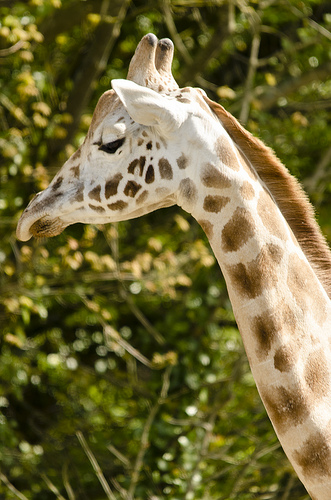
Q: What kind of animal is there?
A: Giraffe.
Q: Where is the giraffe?
A: Outside somewhere.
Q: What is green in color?
A: The leaves.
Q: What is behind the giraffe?
A: Trees.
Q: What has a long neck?
A: Animal.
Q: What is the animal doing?
A: Standing.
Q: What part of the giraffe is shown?
A: Head.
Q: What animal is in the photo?
A: Giraffe.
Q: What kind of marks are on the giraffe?
A: Spots.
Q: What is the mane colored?
A: Brown.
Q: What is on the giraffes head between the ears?
A: Horns.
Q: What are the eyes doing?
A: Shutting.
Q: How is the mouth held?
A: Shut.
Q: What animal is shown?
A: Giraffe.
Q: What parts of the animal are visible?
A: Head and neck.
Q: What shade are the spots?
A: Brown.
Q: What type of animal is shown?
A: Giraffe.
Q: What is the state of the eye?
A: Closed.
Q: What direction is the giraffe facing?
A: Left.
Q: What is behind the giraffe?
A: Trees.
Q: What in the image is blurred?
A: Background.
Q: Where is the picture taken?
A: In a zoo.